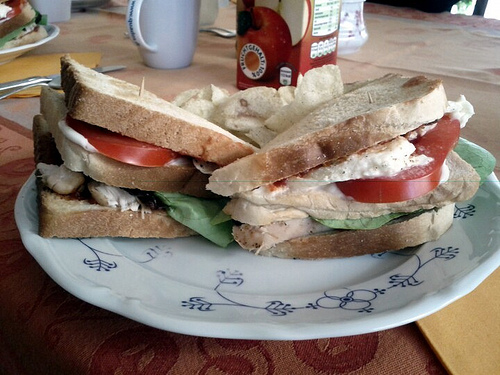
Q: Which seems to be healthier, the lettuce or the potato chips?
A: The lettuce is healthier than the potato chips.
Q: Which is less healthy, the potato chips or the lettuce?
A: The potato chips is less healthy than the lettuce.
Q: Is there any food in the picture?
A: Yes, there is food.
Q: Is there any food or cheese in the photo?
A: Yes, there is food.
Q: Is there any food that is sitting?
A: Yes, there is food that is sitting.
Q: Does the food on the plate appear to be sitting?
A: Yes, the food is sitting.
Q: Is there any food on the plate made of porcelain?
A: Yes, there is food on the plate.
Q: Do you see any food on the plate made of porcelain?
A: Yes, there is food on the plate.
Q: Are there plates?
A: Yes, there is a plate.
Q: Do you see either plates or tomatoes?
A: Yes, there is a plate.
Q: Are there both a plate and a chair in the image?
A: No, there is a plate but no chairs.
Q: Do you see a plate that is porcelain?
A: Yes, there is a porcelain plate.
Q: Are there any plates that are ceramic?
A: Yes, there is a plate that is ceramic.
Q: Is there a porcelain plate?
A: Yes, there is a plate that is made of porcelain.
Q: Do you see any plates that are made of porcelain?
A: Yes, there is a plate that is made of porcelain.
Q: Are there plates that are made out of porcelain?
A: Yes, there is a plate that is made of porcelain.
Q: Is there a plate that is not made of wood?
A: Yes, there is a plate that is made of porcelain.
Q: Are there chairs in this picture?
A: No, there are no chairs.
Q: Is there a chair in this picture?
A: No, there are no chairs.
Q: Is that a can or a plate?
A: That is a plate.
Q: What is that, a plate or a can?
A: That is a plate.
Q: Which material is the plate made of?
A: The plate is made of porcelain.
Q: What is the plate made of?
A: The plate is made of porcelain.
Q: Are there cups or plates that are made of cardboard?
A: No, there is a plate but it is made of porcelain.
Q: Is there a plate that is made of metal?
A: No, there is a plate but it is made of porcelain.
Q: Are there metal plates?
A: No, there is a plate but it is made of porcelain.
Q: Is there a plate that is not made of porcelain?
A: No, there is a plate but it is made of porcelain.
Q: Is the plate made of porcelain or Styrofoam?
A: The plate is made of porcelain.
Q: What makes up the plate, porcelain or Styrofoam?
A: The plate is made of porcelain.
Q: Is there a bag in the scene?
A: No, there are no bags.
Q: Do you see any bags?
A: No, there are no bags.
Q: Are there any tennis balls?
A: No, there are no tennis balls.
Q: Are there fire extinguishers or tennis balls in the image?
A: No, there are no tennis balls or fire extinguishers.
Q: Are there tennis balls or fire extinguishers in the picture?
A: No, there are no tennis balls or fire extinguishers.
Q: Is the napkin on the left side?
A: Yes, the napkin is on the left of the image.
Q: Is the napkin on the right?
A: No, the napkin is on the left of the image.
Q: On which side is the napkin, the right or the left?
A: The napkin is on the left of the image.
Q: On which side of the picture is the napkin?
A: The napkin is on the left of the image.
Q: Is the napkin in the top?
A: Yes, the napkin is in the top of the image.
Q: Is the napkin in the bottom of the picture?
A: No, the napkin is in the top of the image.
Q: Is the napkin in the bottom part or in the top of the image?
A: The napkin is in the top of the image.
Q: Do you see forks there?
A: Yes, there is a fork.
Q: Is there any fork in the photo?
A: Yes, there is a fork.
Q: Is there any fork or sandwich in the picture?
A: Yes, there is a fork.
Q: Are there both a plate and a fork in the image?
A: Yes, there are both a fork and a plate.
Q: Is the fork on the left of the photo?
A: Yes, the fork is on the left of the image.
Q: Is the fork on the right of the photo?
A: No, the fork is on the left of the image.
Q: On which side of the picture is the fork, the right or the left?
A: The fork is on the left of the image.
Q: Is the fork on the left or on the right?
A: The fork is on the left of the image.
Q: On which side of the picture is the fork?
A: The fork is on the left of the image.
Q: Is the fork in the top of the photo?
A: Yes, the fork is in the top of the image.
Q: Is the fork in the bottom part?
A: No, the fork is in the top of the image.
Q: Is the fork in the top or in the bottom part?
A: The fork is in the top of the image.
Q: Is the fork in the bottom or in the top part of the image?
A: The fork is in the top of the image.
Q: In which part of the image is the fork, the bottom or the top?
A: The fork is in the top of the image.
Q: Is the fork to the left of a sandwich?
A: Yes, the fork is to the left of a sandwich.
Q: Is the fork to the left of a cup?
A: No, the fork is to the left of a sandwich.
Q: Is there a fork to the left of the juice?
A: Yes, there is a fork to the left of the juice.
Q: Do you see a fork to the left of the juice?
A: Yes, there is a fork to the left of the juice.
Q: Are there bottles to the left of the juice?
A: No, there is a fork to the left of the juice.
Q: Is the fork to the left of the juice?
A: Yes, the fork is to the left of the juice.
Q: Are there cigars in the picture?
A: No, there are no cigars.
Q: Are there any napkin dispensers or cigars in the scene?
A: No, there are no cigars or napkin dispensers.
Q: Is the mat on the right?
A: Yes, the mat is on the right of the image.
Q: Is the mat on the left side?
A: No, the mat is on the right of the image.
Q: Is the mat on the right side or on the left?
A: The mat is on the right of the image.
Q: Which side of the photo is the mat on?
A: The mat is on the right of the image.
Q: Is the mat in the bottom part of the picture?
A: Yes, the mat is in the bottom of the image.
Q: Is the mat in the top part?
A: No, the mat is in the bottom of the image.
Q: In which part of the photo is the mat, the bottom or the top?
A: The mat is in the bottom of the image.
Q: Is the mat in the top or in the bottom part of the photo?
A: The mat is in the bottom of the image.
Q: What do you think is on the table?
A: The mat is on the table.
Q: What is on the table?
A: The mat is on the table.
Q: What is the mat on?
A: The mat is on the table.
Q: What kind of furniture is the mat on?
A: The mat is on the table.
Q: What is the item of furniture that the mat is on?
A: The piece of furniture is a table.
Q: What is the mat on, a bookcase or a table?
A: The mat is on a table.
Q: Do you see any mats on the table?
A: Yes, there is a mat on the table.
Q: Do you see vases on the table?
A: No, there is a mat on the table.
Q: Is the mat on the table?
A: Yes, the mat is on the table.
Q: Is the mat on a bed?
A: No, the mat is on the table.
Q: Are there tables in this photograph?
A: Yes, there is a table.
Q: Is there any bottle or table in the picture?
A: Yes, there is a table.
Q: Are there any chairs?
A: No, there are no chairs.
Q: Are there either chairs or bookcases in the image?
A: No, there are no chairs or bookcases.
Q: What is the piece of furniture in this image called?
A: The piece of furniture is a table.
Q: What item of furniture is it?
A: The piece of furniture is a table.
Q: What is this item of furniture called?
A: This is a table.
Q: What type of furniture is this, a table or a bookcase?
A: This is a table.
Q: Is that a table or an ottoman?
A: That is a table.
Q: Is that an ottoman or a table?
A: That is a table.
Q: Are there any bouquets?
A: No, there are no bouquets.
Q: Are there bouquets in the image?
A: No, there are no bouquets.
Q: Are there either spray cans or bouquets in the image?
A: No, there are no bouquets or spray cans.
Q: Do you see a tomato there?
A: Yes, there is a tomato.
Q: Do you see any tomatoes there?
A: Yes, there is a tomato.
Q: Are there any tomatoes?
A: Yes, there is a tomato.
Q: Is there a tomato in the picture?
A: Yes, there is a tomato.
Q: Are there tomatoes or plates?
A: Yes, there is a tomato.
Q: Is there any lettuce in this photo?
A: Yes, there is lettuce.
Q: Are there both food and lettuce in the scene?
A: Yes, there are both lettuce and food.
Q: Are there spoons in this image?
A: No, there are no spoons.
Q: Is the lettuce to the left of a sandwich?
A: Yes, the lettuce is to the left of a sandwich.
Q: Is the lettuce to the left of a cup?
A: No, the lettuce is to the left of a sandwich.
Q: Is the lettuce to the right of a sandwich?
A: No, the lettuce is to the left of a sandwich.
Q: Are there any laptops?
A: No, there are no laptops.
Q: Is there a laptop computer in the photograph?
A: No, there are no laptops.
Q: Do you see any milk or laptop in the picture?
A: No, there are no laptops or milk.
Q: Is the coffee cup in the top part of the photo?
A: Yes, the coffee cup is in the top of the image.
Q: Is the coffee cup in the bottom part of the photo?
A: No, the coffee cup is in the top of the image.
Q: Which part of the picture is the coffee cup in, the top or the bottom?
A: The coffee cup is in the top of the image.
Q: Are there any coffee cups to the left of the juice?
A: Yes, there is a coffee cup to the left of the juice.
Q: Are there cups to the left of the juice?
A: No, there is a coffee cup to the left of the juice.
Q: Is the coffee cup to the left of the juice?
A: Yes, the coffee cup is to the left of the juice.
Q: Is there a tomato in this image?
A: Yes, there is a tomato.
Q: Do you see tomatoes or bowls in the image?
A: Yes, there is a tomato.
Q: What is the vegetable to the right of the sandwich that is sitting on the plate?
A: The vegetable is a tomato.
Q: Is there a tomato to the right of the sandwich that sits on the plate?
A: Yes, there is a tomato to the right of the sandwich.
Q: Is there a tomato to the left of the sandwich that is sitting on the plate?
A: No, the tomato is to the right of the sandwich.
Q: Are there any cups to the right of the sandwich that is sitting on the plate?
A: No, there is a tomato to the right of the sandwich.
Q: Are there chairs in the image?
A: No, there are no chairs.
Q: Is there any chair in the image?
A: No, there are no chairs.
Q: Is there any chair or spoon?
A: No, there are no chairs or spoons.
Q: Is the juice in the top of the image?
A: Yes, the juice is in the top of the image.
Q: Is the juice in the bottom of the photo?
A: No, the juice is in the top of the image.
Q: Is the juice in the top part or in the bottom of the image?
A: The juice is in the top of the image.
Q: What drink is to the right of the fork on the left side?
A: The drink is juice.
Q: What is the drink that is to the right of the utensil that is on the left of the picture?
A: The drink is juice.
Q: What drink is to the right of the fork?
A: The drink is juice.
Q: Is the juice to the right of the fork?
A: Yes, the juice is to the right of the fork.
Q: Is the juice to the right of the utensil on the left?
A: Yes, the juice is to the right of the fork.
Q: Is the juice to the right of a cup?
A: No, the juice is to the right of the fork.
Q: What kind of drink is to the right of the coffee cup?
A: The drink is juice.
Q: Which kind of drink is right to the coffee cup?
A: The drink is juice.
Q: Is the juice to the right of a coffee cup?
A: Yes, the juice is to the right of a coffee cup.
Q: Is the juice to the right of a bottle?
A: No, the juice is to the right of a coffee cup.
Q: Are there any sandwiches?
A: Yes, there is a sandwich.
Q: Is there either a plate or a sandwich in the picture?
A: Yes, there is a sandwich.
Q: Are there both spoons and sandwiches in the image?
A: No, there is a sandwich but no spoons.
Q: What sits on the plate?
A: The sandwich sits on the plate.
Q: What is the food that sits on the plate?
A: The food is a sandwich.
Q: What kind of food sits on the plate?
A: The food is a sandwich.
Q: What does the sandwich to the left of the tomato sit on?
A: The sandwich sits on the plate.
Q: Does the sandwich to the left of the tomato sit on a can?
A: No, the sandwich sits on the plate.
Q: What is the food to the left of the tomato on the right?
A: The food is a sandwich.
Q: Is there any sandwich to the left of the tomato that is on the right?
A: Yes, there is a sandwich to the left of the tomato.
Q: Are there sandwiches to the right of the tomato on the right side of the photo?
A: No, the sandwich is to the left of the tomato.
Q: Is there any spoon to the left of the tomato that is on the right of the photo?
A: No, there is a sandwich to the left of the tomato.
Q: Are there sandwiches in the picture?
A: Yes, there is a sandwich.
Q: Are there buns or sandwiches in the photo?
A: Yes, there is a sandwich.